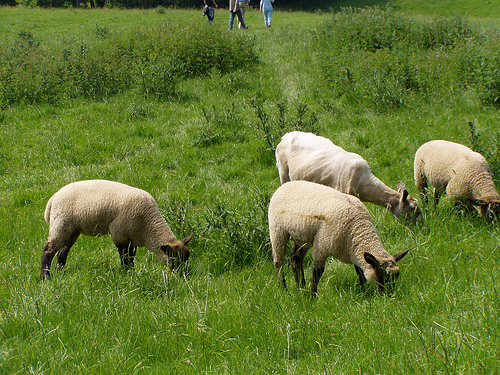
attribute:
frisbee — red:
[247, 3, 250, 7]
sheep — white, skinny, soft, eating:
[275, 131, 425, 227]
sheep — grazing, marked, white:
[266, 182, 410, 304]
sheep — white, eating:
[40, 177, 195, 281]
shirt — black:
[204, 0, 215, 7]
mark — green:
[277, 210, 328, 223]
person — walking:
[202, 2, 220, 27]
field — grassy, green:
[2, 7, 500, 373]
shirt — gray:
[228, 0, 240, 12]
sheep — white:
[413, 138, 500, 222]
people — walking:
[201, 2, 274, 29]